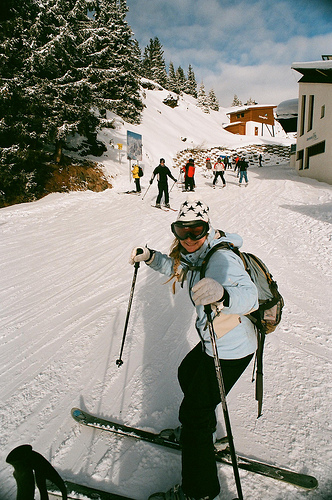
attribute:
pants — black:
[177, 338, 254, 498]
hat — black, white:
[161, 199, 224, 244]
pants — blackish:
[168, 342, 252, 499]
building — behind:
[289, 55, 330, 184]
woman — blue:
[170, 199, 212, 257]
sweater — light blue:
[145, 225, 260, 360]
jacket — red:
[183, 165, 194, 177]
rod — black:
[115, 247, 143, 366]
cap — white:
[168, 198, 213, 225]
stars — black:
[180, 201, 202, 217]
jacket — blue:
[148, 241, 263, 357]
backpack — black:
[135, 165, 144, 176]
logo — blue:
[72, 407, 80, 417]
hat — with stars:
[172, 192, 220, 224]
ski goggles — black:
[170, 219, 211, 239]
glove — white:
[192, 278, 226, 303]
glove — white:
[126, 240, 149, 263]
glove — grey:
[190, 279, 224, 307]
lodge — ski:
[222, 103, 277, 135]